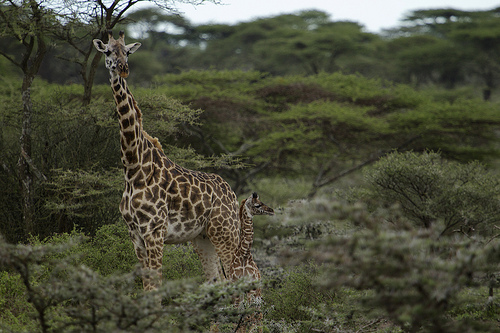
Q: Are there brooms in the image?
A: No, there are no brooms.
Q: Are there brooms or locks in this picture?
A: No, there are no brooms or locks.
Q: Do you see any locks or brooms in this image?
A: No, there are no brooms or locks.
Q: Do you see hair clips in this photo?
A: No, there are no hair clips.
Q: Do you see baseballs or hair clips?
A: No, there are no hair clips or baseballs.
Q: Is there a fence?
A: No, there are no fences.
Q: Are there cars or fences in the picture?
A: No, there are no fences or cars.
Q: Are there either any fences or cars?
A: No, there are no fences or cars.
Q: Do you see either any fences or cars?
A: No, there are no fences or cars.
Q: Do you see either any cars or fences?
A: No, there are no fences or cars.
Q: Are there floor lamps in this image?
A: No, there are no floor lamps.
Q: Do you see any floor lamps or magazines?
A: No, there are no floor lamps or magazines.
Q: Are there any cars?
A: No, there are no cars.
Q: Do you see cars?
A: No, there are no cars.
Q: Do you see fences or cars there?
A: No, there are no cars or fences.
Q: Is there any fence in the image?
A: No, there are no fences.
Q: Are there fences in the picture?
A: No, there are no fences.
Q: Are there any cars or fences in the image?
A: No, there are no fences or cars.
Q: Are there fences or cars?
A: No, there are no fences or cars.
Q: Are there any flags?
A: No, there are no flags.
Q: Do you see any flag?
A: No, there are no flags.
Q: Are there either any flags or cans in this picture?
A: No, there are no flags or cans.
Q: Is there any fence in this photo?
A: No, there are no fences.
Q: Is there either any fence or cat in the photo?
A: No, there are no fences or cats.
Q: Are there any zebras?
A: Yes, there is a zebra.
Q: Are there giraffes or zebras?
A: Yes, there is a zebra.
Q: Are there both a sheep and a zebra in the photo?
A: No, there is a zebra but no sheep.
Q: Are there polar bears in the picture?
A: No, there are no polar bears.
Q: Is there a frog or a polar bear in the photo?
A: No, there are no polar bears or frogs.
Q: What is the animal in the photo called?
A: The animal is a zebra.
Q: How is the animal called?
A: The animal is a zebra.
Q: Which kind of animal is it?
A: The animal is a zebra.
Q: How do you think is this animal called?
A: This is a zebra.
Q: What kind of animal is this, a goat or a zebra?
A: This is a zebra.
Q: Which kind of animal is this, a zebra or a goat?
A: This is a zebra.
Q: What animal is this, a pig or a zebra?
A: This is a zebra.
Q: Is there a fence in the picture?
A: No, there are no fences.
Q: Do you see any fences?
A: No, there are no fences.